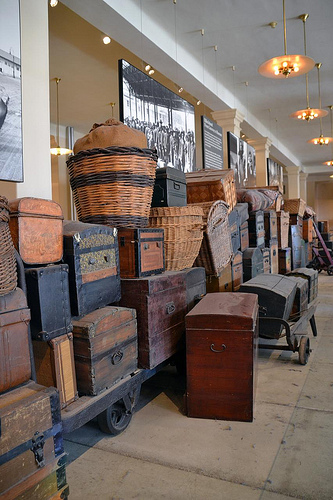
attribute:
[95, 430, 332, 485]
floor — concrete, tan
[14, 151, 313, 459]
pile — trunks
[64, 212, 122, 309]
trunk — hump back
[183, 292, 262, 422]
box — wooden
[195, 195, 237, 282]
basket — wicker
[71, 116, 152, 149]
sack — burlap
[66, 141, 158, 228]
basket — brown, black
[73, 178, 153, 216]
basket — brown, middle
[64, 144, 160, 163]
top — black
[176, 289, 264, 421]
crate — brown, wooden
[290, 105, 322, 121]
light — bright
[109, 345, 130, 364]
handle — black 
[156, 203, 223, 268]
basket — brown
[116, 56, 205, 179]
photo — white, black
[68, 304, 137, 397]
trunk — wooden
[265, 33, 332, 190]
lights — hanging